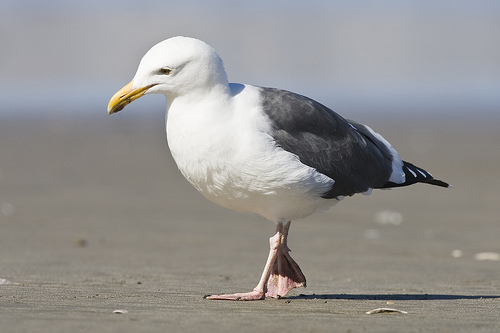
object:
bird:
[106, 34, 454, 302]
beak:
[106, 79, 161, 116]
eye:
[159, 68, 171, 76]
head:
[106, 35, 229, 116]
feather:
[294, 128, 331, 153]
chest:
[164, 102, 244, 192]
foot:
[203, 290, 264, 301]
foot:
[263, 242, 307, 300]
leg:
[255, 220, 283, 291]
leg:
[278, 219, 290, 250]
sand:
[1, 195, 195, 332]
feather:
[168, 110, 193, 146]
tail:
[418, 166, 455, 189]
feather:
[264, 87, 292, 98]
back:
[230, 81, 415, 168]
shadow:
[280, 292, 499, 300]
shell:
[365, 307, 408, 315]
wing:
[259, 86, 432, 190]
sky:
[232, 0, 499, 83]